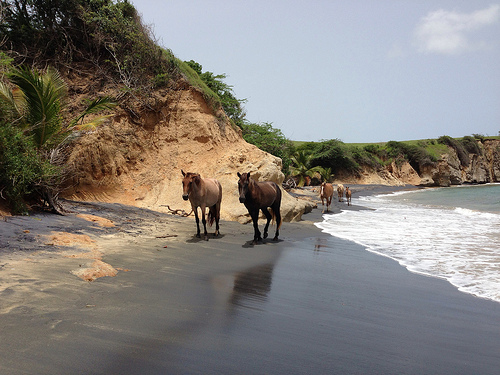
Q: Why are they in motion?
A: Walking.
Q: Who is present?
A: No one.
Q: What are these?
A: Horses.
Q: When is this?
A: Daytime.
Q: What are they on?
A: Sand.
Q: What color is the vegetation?
A: Green.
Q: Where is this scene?
A: At the beach.